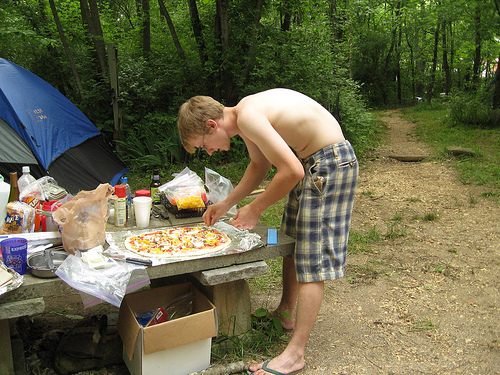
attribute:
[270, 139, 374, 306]
shorts — long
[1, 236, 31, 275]
cup — blue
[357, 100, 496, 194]
grass — green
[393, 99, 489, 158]
ground — COMPLETELY FUCKING IRRELEVANT, brown, white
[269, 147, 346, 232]
pants — short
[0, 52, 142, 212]
tent — large, blue, black, gray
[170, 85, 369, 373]
man — shirtless, bent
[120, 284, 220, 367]
cardboard — full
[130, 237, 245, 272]
pizza — round, uncooked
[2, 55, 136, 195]
tent — blue,black and grey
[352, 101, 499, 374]
path — tan, dirt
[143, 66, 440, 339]
person — enjoying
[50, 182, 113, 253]
bag — tan, plastic, grocery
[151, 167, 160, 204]
bottle — brown, glass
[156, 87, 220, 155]
cut hair — short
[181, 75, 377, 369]
person — having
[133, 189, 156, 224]
cup — white, styrofoam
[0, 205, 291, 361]
table — under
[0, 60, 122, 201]
tent — blue, white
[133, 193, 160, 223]
cup — white, styrofoam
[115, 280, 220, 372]
box — large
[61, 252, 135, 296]
bag — plastic